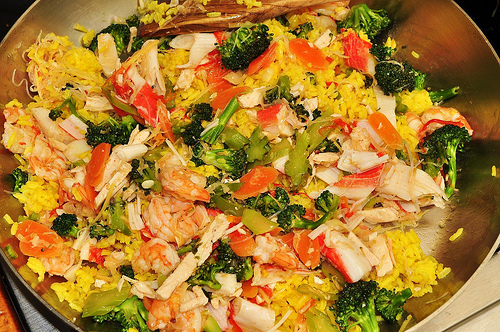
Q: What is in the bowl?
A: Seafood salad delight.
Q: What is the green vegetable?
A: Broccoli.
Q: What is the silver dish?
A: A skillet.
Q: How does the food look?
A: Fresh and delicious.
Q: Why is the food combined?
A: A recipe.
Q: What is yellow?
A: Rice.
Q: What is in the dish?
A: Food.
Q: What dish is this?
A: Salad.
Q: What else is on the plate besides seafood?
A: Vegetables.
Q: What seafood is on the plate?
A: Crab and shrimp.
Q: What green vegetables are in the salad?
A: Broccoli.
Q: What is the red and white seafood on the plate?
A: Crab meat.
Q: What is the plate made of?
A: Metal.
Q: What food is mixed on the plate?
A: Seafood and vegetables.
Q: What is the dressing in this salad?
A: None.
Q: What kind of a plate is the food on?
A: Metal bowl.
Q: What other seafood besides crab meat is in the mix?
A: Shrimp.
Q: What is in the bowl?
A: Food.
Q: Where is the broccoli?
A: In the bowl.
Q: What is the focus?
A: Stir fry.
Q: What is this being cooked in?
A: Wok.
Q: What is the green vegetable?
A: Broccoli.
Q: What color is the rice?
A: Yellow.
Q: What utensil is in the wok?
A: Wooden spatula.